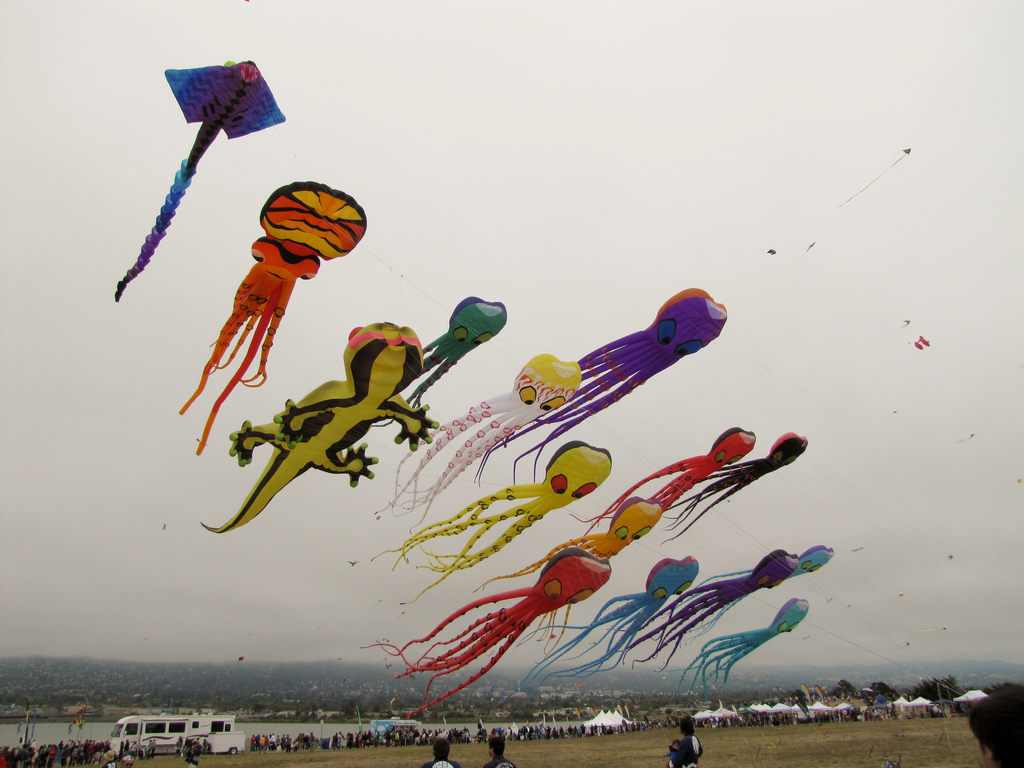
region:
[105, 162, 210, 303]
kite has a long tail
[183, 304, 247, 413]
kite has a long tail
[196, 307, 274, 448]
kite has a long tail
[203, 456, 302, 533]
kite has a long tail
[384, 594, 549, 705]
kite has a long tail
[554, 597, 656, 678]
kite has a long tail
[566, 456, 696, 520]
kite has a long tail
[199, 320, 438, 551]
the yellow lizard kite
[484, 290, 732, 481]
the purple big octopus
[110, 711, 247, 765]
thge white rv in the field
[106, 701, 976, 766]
the field under all the kites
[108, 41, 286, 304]
the purple sting ray kite in the air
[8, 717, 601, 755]
the water behind the RV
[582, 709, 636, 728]
the white canopy with three points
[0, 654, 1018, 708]
the hill in the fog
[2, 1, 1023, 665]
the sky is muggy and full of kites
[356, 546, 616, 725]
The red octopus kite on the bottom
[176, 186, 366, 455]
the kite is orange and black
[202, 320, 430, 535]
the kite is yellow and black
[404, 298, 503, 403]
the kite is green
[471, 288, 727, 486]
the kite is purple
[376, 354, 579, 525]
the kite is white and red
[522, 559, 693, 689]
the kite is blue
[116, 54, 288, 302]
the kite is purple and blue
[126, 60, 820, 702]
the kite is in the air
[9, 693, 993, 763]
the people are standing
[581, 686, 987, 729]
white tents on the grass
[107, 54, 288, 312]
blue kite shaped like a manta ray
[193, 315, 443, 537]
green and yellow kite shaped like a lizard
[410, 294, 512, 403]
green kite shaped like an octopus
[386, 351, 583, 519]
white kite shaped like an octopus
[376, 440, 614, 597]
yellow kite shaped like an octopus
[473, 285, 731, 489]
purple kite shaped like an octopus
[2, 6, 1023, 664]
sky is gray and overcast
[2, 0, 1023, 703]
kites are in the sky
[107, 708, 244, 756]
white RV is parked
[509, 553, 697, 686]
blue kite shaped like an octopus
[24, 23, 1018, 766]
there are colorful kites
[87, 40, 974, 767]
the kites look like animals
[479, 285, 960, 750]
these kites look like octopi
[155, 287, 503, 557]
this kite is shaped like a lizard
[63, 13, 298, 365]
this kite is shaped like a stingray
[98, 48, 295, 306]
Closest purple kite with a long tail.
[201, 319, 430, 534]
Black and yellow lizard kite.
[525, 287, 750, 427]
Closest purple octopus kite.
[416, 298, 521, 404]
Green octopus kite near a white one.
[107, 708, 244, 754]
Large RV parked in the grass.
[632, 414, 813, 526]
Black and red octopus kites together.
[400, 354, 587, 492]
White octopus kite in the middle.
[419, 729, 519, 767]
Two men together in the middle.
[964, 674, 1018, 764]
Head in the bottom right corner.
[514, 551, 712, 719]
A kite in the air.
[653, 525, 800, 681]
A kite in the air.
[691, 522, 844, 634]
A kite in the air.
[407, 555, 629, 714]
A kite in the air.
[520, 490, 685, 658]
A kite in the air.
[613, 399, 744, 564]
A kite in the air.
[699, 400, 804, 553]
A kite in the air.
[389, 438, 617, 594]
A kite in the air.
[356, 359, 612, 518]
A kite in the air.